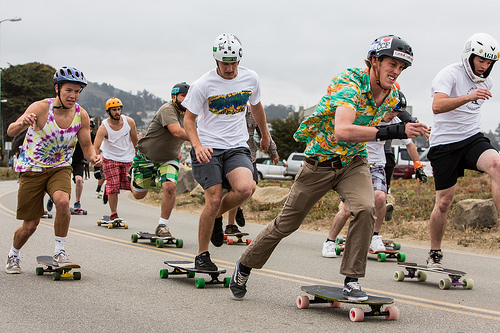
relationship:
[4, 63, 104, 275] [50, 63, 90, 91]
man in helmet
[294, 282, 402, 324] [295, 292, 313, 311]
skateboard with wheel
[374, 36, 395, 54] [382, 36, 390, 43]
sticker has heart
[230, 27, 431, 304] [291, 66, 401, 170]
man in shirt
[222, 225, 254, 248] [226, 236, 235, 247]
skateboard has wheel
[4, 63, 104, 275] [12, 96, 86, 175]
man in tank top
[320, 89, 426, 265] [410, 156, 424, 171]
man with orange band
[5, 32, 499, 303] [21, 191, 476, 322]
guys on skateboards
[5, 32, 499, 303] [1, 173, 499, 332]
guys racing on road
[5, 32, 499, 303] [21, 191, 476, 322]
guys racing on skateboards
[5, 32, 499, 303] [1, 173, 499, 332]
guys skateboard on street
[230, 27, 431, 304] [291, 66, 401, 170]
skateboarder in bright shirt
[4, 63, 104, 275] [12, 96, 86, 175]
skateboarder in tie-dye top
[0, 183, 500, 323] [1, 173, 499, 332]
stripes on road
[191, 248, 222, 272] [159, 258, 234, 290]
foot on skateboard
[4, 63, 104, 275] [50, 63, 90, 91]
man wearing helmet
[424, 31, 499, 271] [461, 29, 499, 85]
man wearing helmet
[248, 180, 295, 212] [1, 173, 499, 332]
rock beside road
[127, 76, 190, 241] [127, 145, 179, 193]
man wearing shorts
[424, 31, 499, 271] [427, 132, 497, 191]
man wearing shorts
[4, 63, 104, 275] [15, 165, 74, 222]
man wearing shorts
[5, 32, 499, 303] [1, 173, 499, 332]
skateboarders on road